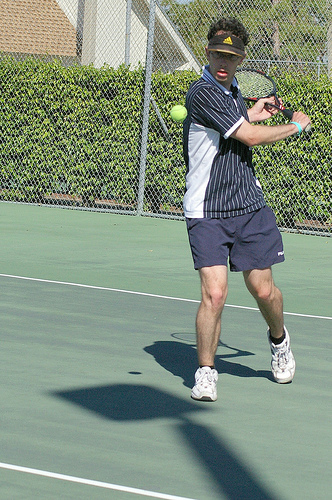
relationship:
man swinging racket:
[177, 12, 312, 404] [233, 66, 311, 133]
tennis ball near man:
[166, 103, 188, 127] [177, 12, 312, 404]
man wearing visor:
[177, 12, 312, 404] [204, 32, 248, 62]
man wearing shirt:
[177, 12, 312, 404] [181, 64, 267, 220]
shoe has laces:
[265, 324, 295, 383] [195, 364, 216, 385]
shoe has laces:
[265, 322, 297, 386] [271, 341, 290, 367]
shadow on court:
[143, 327, 292, 406] [1, 199, 329, 499]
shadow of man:
[143, 327, 292, 406] [177, 12, 312, 404]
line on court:
[1, 270, 331, 325] [1, 199, 329, 499]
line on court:
[1, 456, 203, 500] [1, 199, 329, 499]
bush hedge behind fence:
[1, 55, 331, 225] [1, 0, 331, 239]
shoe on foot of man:
[265, 324, 295, 383] [177, 12, 312, 404]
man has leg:
[177, 12, 312, 404] [191, 226, 232, 384]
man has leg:
[177, 12, 312, 404] [234, 216, 287, 345]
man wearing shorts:
[177, 12, 312, 404] [183, 204, 286, 273]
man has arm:
[177, 12, 312, 404] [193, 88, 309, 150]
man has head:
[177, 12, 312, 404] [202, 17, 249, 81]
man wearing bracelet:
[177, 12, 312, 404] [287, 119, 304, 137]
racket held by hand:
[233, 66, 311, 133] [290, 107, 311, 134]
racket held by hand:
[233, 66, 311, 133] [251, 94, 282, 121]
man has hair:
[177, 12, 312, 404] [205, 15, 251, 46]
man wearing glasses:
[177, 12, 312, 404] [205, 48, 241, 62]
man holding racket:
[177, 12, 312, 404] [233, 66, 311, 133]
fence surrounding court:
[1, 0, 331, 239] [1, 199, 329, 499]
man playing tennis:
[177, 12, 312, 404] [169, 64, 314, 138]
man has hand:
[177, 12, 312, 404] [290, 107, 311, 134]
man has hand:
[177, 12, 312, 404] [251, 94, 282, 121]